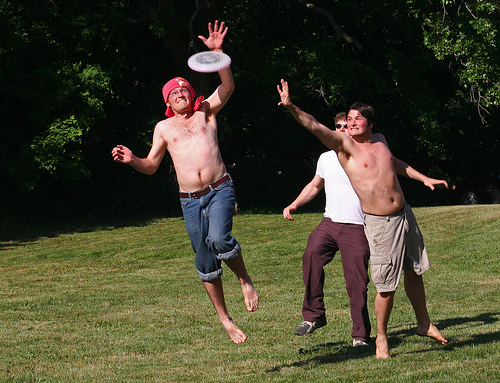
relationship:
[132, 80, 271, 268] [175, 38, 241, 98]
man with frisbee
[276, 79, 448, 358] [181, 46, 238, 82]
man with frisbee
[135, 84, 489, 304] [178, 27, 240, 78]
men with frisbee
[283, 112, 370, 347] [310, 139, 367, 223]
man wearing shirt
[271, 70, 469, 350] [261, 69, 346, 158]
man stretching arm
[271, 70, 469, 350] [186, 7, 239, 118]
man stretching arm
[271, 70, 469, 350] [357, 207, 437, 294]
man wearing shorts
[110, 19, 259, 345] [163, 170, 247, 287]
man wearing jeans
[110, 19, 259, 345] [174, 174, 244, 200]
man wearing belt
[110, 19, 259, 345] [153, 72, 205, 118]
man wearing shirt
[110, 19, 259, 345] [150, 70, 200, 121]
man has head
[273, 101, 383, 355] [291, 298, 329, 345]
man has foot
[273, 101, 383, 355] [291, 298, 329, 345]
man raised foot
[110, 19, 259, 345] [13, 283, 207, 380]
man jumping off ground